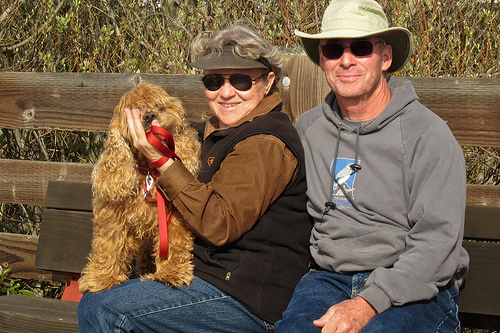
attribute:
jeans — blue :
[95, 267, 267, 331]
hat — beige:
[295, 1, 413, 71]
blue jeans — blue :
[287, 271, 442, 331]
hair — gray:
[185, 24, 292, 69]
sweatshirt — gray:
[290, 74, 470, 312]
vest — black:
[157, 91, 308, 306]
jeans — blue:
[94, 295, 249, 332]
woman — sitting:
[180, 25, 302, 312]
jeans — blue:
[272, 261, 447, 328]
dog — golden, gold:
[78, 84, 203, 294]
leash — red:
[131, 125, 180, 269]